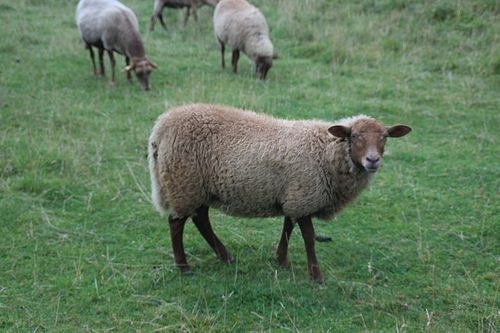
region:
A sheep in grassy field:
[140, 96, 415, 286]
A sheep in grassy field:
[145, 97, 417, 292]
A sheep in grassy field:
[145, 95, 421, 295]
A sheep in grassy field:
[145, 97, 415, 282]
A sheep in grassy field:
[145, 96, 415, 287]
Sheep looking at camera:
[145, 97, 422, 285]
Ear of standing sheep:
[322, 117, 353, 139]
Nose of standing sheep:
[361, 157, 385, 166]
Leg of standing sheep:
[301, 222, 328, 287]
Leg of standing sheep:
[273, 220, 297, 272]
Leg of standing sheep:
[196, 210, 245, 267]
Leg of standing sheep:
[164, 217, 193, 283]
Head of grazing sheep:
[119, 58, 161, 88]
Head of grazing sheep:
[246, 45, 280, 80]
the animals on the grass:
[75, 0, 410, 281]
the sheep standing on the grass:
[149, 102, 412, 284]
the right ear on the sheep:
[327, 124, 350, 137]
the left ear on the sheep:
[385, 124, 412, 138]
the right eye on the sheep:
[350, 133, 355, 138]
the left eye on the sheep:
[381, 133, 388, 138]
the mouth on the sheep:
[364, 165, 379, 171]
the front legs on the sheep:
[275, 199, 323, 282]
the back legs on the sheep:
[167, 204, 234, 273]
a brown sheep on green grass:
[140, 85, 417, 286]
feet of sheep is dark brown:
[153, 208, 337, 286]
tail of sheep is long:
[142, 118, 172, 216]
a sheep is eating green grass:
[207, 0, 287, 87]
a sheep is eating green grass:
[67, 2, 166, 97]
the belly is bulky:
[71, 9, 114, 53]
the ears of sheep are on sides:
[322, 116, 414, 139]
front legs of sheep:
[273, 210, 325, 282]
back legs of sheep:
[161, 210, 240, 280]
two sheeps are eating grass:
[67, 2, 299, 99]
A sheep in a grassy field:
[138, 91, 418, 291]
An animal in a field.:
[146, 102, 414, 297]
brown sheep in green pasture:
[135, 99, 403, 289]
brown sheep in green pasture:
[68, 2, 155, 93]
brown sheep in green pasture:
[203, 2, 285, 79]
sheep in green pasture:
[145, 94, 411, 283]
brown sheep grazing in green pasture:
[71, 2, 161, 96]